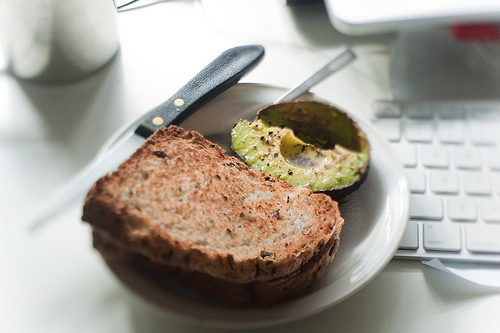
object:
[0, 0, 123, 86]
salt shaker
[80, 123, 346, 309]
two pieces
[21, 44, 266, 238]
knife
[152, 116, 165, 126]
bolt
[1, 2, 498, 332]
desk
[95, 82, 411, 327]
toast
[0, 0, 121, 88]
computer mouse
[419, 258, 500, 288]
paper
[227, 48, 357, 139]
handle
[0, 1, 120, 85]
mug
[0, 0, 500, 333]
table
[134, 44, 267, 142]
handle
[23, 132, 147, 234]
blade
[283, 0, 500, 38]
computer monitor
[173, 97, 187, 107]
bolt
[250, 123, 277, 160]
pepper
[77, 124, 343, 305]
bread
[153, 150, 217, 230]
seasoning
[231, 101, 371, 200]
avocado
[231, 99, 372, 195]
half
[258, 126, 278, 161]
spices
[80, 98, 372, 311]
food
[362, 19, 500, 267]
keyboard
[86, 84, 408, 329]
plate